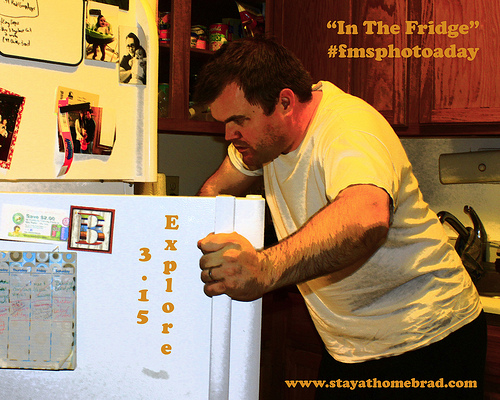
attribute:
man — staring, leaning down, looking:
[195, 32, 490, 397]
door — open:
[3, 188, 264, 397]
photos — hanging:
[49, 72, 125, 158]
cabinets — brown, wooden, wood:
[159, 0, 495, 148]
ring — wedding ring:
[203, 266, 219, 281]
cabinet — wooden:
[158, 0, 270, 140]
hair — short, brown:
[193, 36, 319, 109]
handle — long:
[194, 197, 248, 400]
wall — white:
[163, 133, 498, 229]